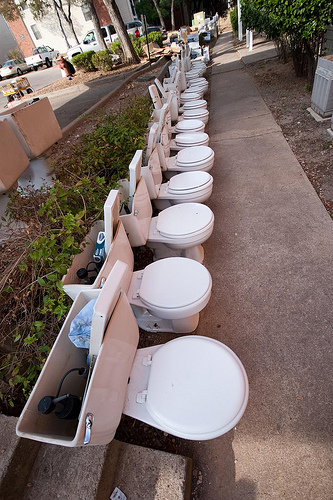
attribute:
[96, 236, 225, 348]
seat — cover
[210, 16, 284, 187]
sidewalk — paved, part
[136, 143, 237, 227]
toilet — seat, white, first, back, concrete, third, four, plumbing, bowl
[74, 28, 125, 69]
car — part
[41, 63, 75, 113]
street — part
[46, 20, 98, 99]
light — red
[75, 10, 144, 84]
truck — white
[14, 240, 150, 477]
tank — water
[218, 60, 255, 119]
step — concrete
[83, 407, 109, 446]
handle — flush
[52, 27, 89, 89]
hydrant — fire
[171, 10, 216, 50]
sign — street